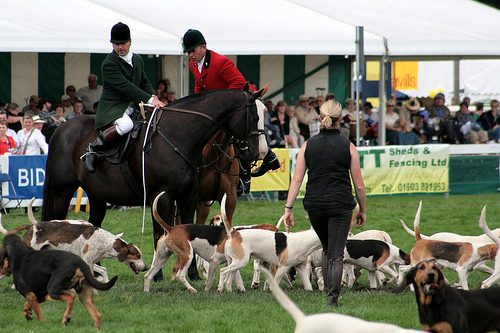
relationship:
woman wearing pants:
[285, 99, 367, 309] [306, 206, 354, 309]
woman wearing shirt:
[285, 99, 367, 309] [304, 129, 358, 211]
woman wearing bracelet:
[285, 99, 367, 309] [285, 205, 294, 211]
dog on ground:
[395, 261, 499, 333] [0, 193, 499, 332]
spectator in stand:
[478, 99, 499, 143] [0, 0, 498, 214]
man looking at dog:
[79, 23, 163, 174] [26, 195, 149, 285]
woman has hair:
[285, 99, 367, 309] [318, 98, 343, 131]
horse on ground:
[41, 81, 264, 284] [0, 193, 499, 332]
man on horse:
[79, 23, 163, 174] [41, 81, 264, 284]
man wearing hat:
[79, 23, 163, 174] [110, 22, 133, 45]